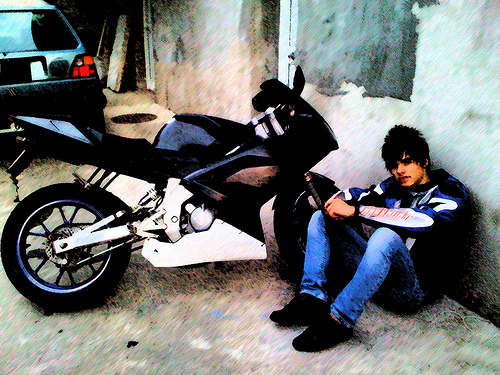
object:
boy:
[270, 124, 467, 351]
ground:
[110, 300, 270, 374]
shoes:
[291, 312, 354, 352]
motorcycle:
[0, 64, 365, 312]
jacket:
[325, 168, 471, 284]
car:
[1, 0, 108, 131]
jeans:
[299, 204, 424, 328]